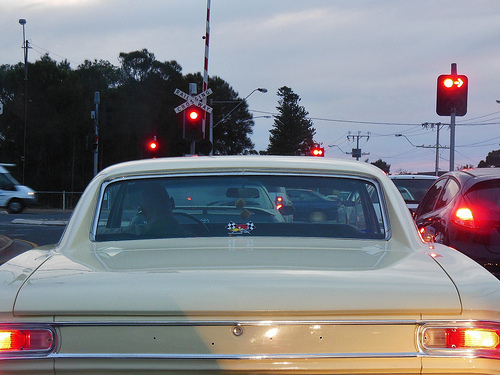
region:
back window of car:
[75, 178, 393, 246]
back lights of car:
[0, 312, 487, 369]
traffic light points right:
[427, 67, 474, 119]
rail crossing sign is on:
[174, 88, 204, 113]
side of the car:
[1, 168, 30, 218]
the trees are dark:
[66, 72, 161, 128]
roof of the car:
[409, 148, 493, 185]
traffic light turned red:
[436, 71, 468, 118]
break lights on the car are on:
[1, 327, 493, 355]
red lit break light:
[453, 201, 483, 226]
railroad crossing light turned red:
[166, 73, 213, 153]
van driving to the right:
[0, 168, 40, 218]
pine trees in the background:
[5, 54, 317, 155]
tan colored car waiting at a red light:
[2, 157, 496, 372]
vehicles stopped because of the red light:
[1, 152, 498, 374]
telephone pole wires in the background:
[228, 106, 495, 165]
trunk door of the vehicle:
[0, 242, 459, 330]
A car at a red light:
[6, 55, 492, 365]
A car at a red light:
[7, 45, 483, 365]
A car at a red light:
[5, 51, 488, 362]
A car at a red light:
[10, 52, 481, 362]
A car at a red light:
[10, 51, 486, 371]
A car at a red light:
[0, 60, 485, 360]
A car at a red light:
[1, 50, 481, 361]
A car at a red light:
[0, 38, 486, 358]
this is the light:
[446, 325, 498, 347]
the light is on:
[436, 320, 498, 353]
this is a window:
[99, 176, 374, 241]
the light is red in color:
[445, 203, 485, 228]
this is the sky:
[330, 7, 414, 91]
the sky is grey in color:
[292, 0, 423, 79]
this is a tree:
[272, 88, 314, 148]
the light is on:
[187, 106, 200, 121]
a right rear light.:
[411, 316, 498, 361]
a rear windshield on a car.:
[91, 164, 393, 249]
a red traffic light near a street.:
[426, 71, 473, 113]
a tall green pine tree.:
[269, 85, 319, 157]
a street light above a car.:
[219, 75, 272, 147]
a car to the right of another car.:
[417, 175, 498, 267]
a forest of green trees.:
[3, 50, 257, 216]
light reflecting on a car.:
[246, 302, 291, 360]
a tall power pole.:
[337, 128, 373, 158]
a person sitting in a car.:
[121, 171, 188, 242]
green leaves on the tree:
[300, 110, 317, 146]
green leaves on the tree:
[266, 111, 287, 143]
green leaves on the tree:
[281, 104, 311, 141]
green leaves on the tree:
[110, 78, 156, 125]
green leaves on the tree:
[92, 118, 162, 184]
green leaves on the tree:
[47, 69, 79, 107]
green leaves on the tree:
[105, 43, 155, 85]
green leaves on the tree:
[98, 86, 158, 142]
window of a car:
[97, 181, 384, 237]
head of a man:
[142, 186, 174, 216]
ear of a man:
[170, 197, 178, 207]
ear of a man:
[140, 206, 148, 217]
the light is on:
[438, 325, 495, 353]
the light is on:
[0, 327, 49, 352]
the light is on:
[187, 110, 200, 120]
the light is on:
[312, 149, 323, 158]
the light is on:
[147, 141, 156, 150]